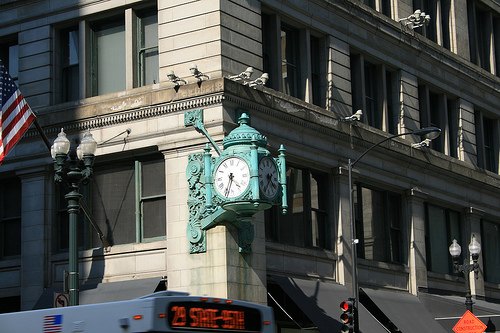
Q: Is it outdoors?
A: Yes, it is outdoors.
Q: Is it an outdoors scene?
A: Yes, it is outdoors.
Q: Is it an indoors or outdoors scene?
A: It is outdoors.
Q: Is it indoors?
A: No, it is outdoors.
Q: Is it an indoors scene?
A: No, it is outdoors.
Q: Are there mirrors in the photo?
A: No, there are no mirrors.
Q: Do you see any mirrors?
A: No, there are no mirrors.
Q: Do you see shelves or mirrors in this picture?
A: No, there are no mirrors or shelves.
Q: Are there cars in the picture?
A: No, there are no cars.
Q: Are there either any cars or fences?
A: No, there are no cars or fences.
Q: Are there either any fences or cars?
A: No, there are no cars or fences.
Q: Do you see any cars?
A: No, there are no cars.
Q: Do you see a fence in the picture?
A: No, there are no fences.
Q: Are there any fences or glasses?
A: No, there are no fences or glasses.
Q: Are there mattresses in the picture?
A: No, there are no mattresses.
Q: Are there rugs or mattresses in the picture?
A: No, there are no mattresses or rugs.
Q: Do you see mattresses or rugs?
A: No, there are no mattresses or rugs.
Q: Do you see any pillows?
A: No, there are no pillows.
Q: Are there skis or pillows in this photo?
A: No, there are no pillows or skis.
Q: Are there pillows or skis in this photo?
A: No, there are no pillows or skis.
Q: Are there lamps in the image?
A: Yes, there is a lamp.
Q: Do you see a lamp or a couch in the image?
A: Yes, there is a lamp.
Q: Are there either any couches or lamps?
A: Yes, there is a lamp.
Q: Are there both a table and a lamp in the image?
A: No, there is a lamp but no tables.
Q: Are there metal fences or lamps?
A: Yes, there is a metal lamp.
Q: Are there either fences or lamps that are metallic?
A: Yes, the lamp is metallic.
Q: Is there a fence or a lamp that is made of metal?
A: Yes, the lamp is made of metal.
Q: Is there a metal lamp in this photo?
A: Yes, there is a metal lamp.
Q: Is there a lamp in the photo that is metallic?
A: Yes, there is a lamp that is metallic.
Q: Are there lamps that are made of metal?
A: Yes, there is a lamp that is made of metal.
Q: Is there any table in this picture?
A: No, there are no tables.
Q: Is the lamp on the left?
A: Yes, the lamp is on the left of the image.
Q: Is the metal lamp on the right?
A: No, the lamp is on the left of the image.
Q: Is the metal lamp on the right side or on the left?
A: The lamp is on the left of the image.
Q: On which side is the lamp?
A: The lamp is on the left of the image.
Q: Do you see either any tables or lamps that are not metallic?
A: No, there is a lamp but it is metallic.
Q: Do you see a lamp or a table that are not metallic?
A: No, there is a lamp but it is metallic.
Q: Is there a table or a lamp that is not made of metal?
A: No, there is a lamp but it is made of metal.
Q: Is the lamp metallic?
A: Yes, the lamp is metallic.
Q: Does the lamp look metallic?
A: Yes, the lamp is metallic.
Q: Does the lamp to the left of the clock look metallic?
A: Yes, the lamp is metallic.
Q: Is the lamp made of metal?
A: Yes, the lamp is made of metal.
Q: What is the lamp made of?
A: The lamp is made of metal.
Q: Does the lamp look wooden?
A: No, the lamp is metallic.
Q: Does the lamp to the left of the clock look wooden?
A: No, the lamp is metallic.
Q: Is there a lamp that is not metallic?
A: No, there is a lamp but it is metallic.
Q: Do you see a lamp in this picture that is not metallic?
A: No, there is a lamp but it is metallic.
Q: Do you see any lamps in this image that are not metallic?
A: No, there is a lamp but it is metallic.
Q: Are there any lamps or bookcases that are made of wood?
A: No, there is a lamp but it is made of metal.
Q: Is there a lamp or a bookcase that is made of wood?
A: No, there is a lamp but it is made of metal.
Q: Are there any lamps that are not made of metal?
A: No, there is a lamp but it is made of metal.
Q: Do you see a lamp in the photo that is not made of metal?
A: No, there is a lamp but it is made of metal.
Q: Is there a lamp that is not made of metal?
A: No, there is a lamp but it is made of metal.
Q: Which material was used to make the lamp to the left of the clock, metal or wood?
A: The lamp is made of metal.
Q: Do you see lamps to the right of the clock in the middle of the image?
A: No, the lamp is to the left of the clock.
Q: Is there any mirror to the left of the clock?
A: No, there is a lamp to the left of the clock.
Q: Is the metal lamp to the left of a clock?
A: Yes, the lamp is to the left of a clock.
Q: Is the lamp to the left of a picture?
A: No, the lamp is to the left of a clock.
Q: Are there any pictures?
A: No, there are no pictures.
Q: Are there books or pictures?
A: No, there are no pictures or books.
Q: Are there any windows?
A: Yes, there is a window.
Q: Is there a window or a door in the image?
A: Yes, there is a window.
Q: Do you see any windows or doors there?
A: Yes, there is a window.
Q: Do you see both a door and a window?
A: No, there is a window but no doors.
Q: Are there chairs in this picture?
A: No, there are no chairs.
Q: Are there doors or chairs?
A: No, there are no chairs or doors.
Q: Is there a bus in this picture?
A: Yes, there is a bus.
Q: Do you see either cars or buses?
A: Yes, there is a bus.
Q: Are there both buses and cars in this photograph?
A: No, there is a bus but no cars.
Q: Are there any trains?
A: No, there are no trains.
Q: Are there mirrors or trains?
A: No, there are no trains or mirrors.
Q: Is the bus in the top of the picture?
A: No, the bus is in the bottom of the image.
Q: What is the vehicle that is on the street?
A: The vehicle is a bus.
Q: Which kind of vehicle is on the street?
A: The vehicle is a bus.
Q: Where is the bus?
A: The bus is on the street.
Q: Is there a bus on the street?
A: Yes, there is a bus on the street.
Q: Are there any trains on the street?
A: No, there is a bus on the street.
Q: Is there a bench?
A: No, there are no benches.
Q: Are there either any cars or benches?
A: No, there are no benches or cars.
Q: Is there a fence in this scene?
A: No, there are no fences.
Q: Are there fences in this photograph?
A: No, there are no fences.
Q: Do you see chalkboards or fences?
A: No, there are no fences or chalkboards.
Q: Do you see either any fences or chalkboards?
A: No, there are no fences or chalkboards.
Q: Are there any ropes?
A: No, there are no ropes.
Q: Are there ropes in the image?
A: No, there are no ropes.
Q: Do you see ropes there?
A: No, there are no ropes.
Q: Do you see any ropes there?
A: No, there are no ropes.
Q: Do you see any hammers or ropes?
A: No, there are no ropes or hammers.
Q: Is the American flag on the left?
A: Yes, the American flag is on the left of the image.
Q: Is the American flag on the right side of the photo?
A: No, the American flag is on the left of the image.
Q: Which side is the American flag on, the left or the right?
A: The American flag is on the left of the image.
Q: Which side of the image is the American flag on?
A: The American flag is on the left of the image.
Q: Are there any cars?
A: No, there are no cars.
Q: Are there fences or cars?
A: No, there are no cars or fences.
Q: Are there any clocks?
A: Yes, there is a clock.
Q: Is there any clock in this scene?
A: Yes, there is a clock.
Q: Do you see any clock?
A: Yes, there is a clock.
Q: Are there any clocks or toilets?
A: Yes, there is a clock.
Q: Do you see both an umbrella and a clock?
A: No, there is a clock but no umbrellas.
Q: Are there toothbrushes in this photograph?
A: No, there are no toothbrushes.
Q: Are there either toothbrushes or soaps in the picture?
A: No, there are no toothbrushes or soaps.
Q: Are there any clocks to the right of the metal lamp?
A: Yes, there is a clock to the right of the lamp.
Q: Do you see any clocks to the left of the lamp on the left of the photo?
A: No, the clock is to the right of the lamp.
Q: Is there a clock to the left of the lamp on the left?
A: No, the clock is to the right of the lamp.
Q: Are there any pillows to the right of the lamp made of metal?
A: No, there is a clock to the right of the lamp.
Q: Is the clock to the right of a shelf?
A: No, the clock is to the right of a lamp.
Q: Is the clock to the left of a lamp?
A: No, the clock is to the right of a lamp.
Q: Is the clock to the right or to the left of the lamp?
A: The clock is to the right of the lamp.